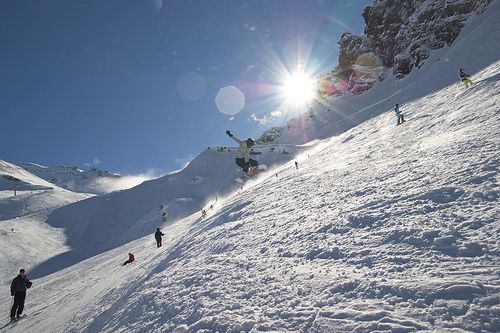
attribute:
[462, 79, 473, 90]
pants — yellow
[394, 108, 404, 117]
coat — blue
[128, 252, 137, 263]
jacket — red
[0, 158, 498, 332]
snow — white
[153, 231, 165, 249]
clothing — dark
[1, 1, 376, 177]
sky — blue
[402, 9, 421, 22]
snow — white